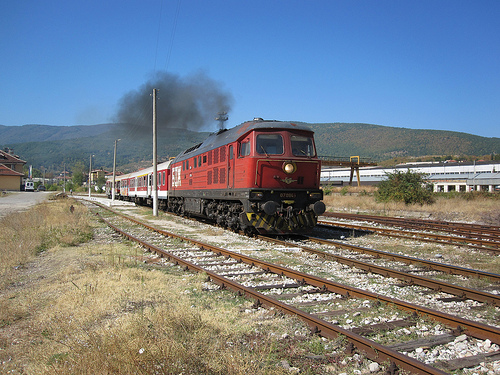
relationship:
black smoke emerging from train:
[101, 63, 237, 149] [109, 119, 327, 239]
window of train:
[289, 134, 318, 159] [109, 119, 327, 239]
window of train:
[255, 131, 286, 156] [109, 119, 327, 239]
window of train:
[238, 139, 250, 159] [109, 119, 327, 239]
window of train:
[228, 144, 234, 159] [109, 119, 327, 239]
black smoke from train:
[101, 63, 237, 149] [109, 119, 327, 239]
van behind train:
[23, 179, 37, 191] [109, 119, 327, 239]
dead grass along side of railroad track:
[0, 288, 94, 371] [65, 190, 498, 373]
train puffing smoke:
[109, 119, 327, 239] [101, 67, 233, 154]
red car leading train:
[165, 118, 331, 240] [109, 119, 327, 239]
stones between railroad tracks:
[328, 257, 363, 286] [315, 288, 499, 372]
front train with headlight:
[240, 114, 329, 242] [281, 160, 294, 171]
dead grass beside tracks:
[1, 188, 498, 371] [67, 193, 497, 373]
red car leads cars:
[167, 114, 331, 240] [104, 153, 168, 205]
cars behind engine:
[105, 156, 166, 205] [170, 118, 330, 240]